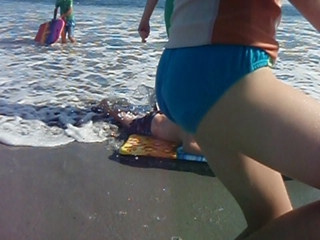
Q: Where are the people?
A: Beach.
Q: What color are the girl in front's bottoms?
A: Blue.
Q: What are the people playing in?
A: Ocean.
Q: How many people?
A: Four.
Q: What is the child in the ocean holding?
A: A board.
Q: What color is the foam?
A: White.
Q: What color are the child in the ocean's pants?
A: Blue.